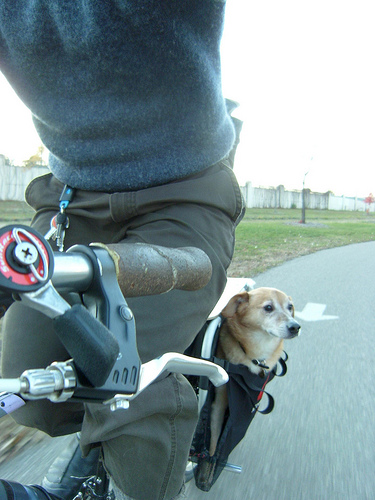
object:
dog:
[209, 283, 297, 458]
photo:
[28, 11, 371, 475]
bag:
[189, 375, 276, 460]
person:
[0, 0, 252, 500]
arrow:
[288, 300, 336, 322]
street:
[274, 241, 373, 463]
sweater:
[16, 10, 236, 198]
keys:
[42, 210, 69, 252]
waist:
[33, 157, 245, 200]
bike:
[2, 230, 290, 496]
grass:
[246, 212, 370, 255]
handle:
[114, 236, 211, 294]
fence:
[244, 192, 345, 210]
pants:
[14, 161, 241, 430]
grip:
[56, 296, 153, 397]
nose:
[288, 318, 304, 337]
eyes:
[264, 303, 275, 311]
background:
[255, 41, 369, 150]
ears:
[221, 294, 252, 324]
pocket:
[197, 170, 248, 232]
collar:
[226, 344, 275, 371]